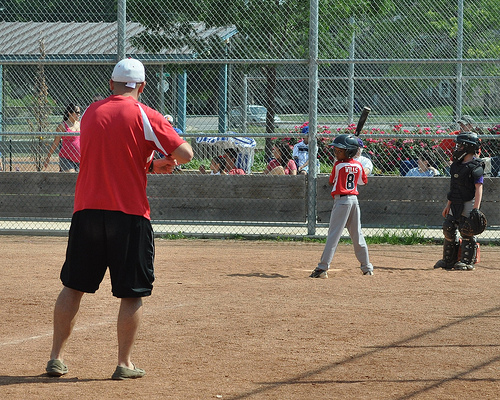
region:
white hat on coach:
[100, 58, 155, 85]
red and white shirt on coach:
[59, 93, 176, 222]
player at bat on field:
[307, 87, 385, 290]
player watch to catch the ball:
[426, 109, 491, 269]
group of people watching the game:
[22, 85, 497, 192]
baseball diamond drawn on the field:
[0, 243, 383, 365]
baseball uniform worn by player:
[312, 158, 377, 280]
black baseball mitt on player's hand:
[460, 205, 489, 242]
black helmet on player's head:
[324, 123, 366, 158]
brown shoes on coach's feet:
[39, 353, 148, 385]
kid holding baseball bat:
[291, 103, 381, 283]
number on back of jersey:
[345, 174, 357, 191]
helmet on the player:
[331, 137, 360, 157]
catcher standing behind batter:
[443, 131, 486, 273]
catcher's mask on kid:
[449, 129, 481, 154]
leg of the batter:
[346, 228, 373, 275]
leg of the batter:
[310, 219, 340, 276]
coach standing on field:
[43, 61, 203, 376]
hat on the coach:
[108, 55, 155, 88]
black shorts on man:
[68, 211, 172, 311]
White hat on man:
[102, 53, 154, 83]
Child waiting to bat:
[314, 130, 386, 277]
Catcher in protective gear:
[432, 130, 487, 271]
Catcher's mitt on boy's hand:
[465, 206, 487, 232]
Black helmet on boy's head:
[334, 133, 364, 150]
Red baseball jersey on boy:
[332, 155, 365, 202]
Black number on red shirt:
[345, 173, 357, 188]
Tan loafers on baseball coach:
[35, 350, 148, 383]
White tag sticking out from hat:
[124, 78, 137, 86]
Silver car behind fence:
[220, 98, 287, 123]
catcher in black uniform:
[439, 121, 490, 276]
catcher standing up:
[437, 120, 487, 277]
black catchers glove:
[461, 202, 487, 241]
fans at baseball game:
[196, 123, 316, 170]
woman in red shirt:
[48, 98, 80, 171]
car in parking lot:
[219, 98, 287, 126]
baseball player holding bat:
[308, 101, 381, 278]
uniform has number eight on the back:
[331, 161, 361, 202]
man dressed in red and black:
[66, 52, 157, 336]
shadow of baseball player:
[208, 231, 376, 290]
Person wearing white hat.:
[108, 49, 160, 99]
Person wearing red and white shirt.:
[77, 102, 194, 196]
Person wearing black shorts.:
[59, 223, 188, 293]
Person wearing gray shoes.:
[33, 346, 182, 398]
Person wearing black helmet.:
[328, 134, 373, 164]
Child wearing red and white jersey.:
[324, 150, 376, 200]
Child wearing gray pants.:
[321, 202, 381, 253]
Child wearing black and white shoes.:
[306, 261, 390, 293]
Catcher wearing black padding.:
[443, 162, 474, 213]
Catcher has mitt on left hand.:
[461, 200, 493, 247]